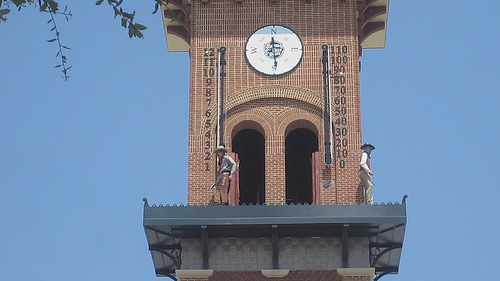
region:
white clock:
[221, 7, 297, 84]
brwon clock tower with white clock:
[183, 9, 378, 196]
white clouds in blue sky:
[91, 77, 135, 130]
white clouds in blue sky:
[59, 171, 95, 190]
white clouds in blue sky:
[10, 209, 73, 247]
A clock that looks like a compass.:
[245, 24, 302, 77]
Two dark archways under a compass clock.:
[228, 113, 321, 206]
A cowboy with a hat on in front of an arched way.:
[210, 143, 235, 203]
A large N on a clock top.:
[267, 25, 273, 35]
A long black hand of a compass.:
[267, 35, 274, 65]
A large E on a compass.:
[290, 46, 300, 51]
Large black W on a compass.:
[251, 45, 257, 55]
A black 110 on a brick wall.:
[329, 44, 348, 54]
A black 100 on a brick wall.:
[331, 53, 348, 64]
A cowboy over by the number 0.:
[356, 141, 375, 205]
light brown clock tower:
[148, 8, 406, 241]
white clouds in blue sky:
[123, 98, 169, 148]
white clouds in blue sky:
[42, 113, 118, 157]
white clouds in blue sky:
[367, 94, 444, 144]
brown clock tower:
[170, 8, 387, 273]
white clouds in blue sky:
[119, 98, 169, 142]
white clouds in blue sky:
[51, 140, 143, 172]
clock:
[234, 10, 322, 80]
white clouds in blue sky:
[20, 85, 77, 133]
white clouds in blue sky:
[413, 26, 475, 58]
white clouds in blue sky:
[393, 78, 444, 125]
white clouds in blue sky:
[390, 129, 420, 163]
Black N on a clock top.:
[268, 26, 277, 37]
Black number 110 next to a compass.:
[329, 45, 347, 55]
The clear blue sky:
[5, 19, 499, 270]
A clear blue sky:
[4, 15, 499, 265]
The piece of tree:
[1, 15, 148, 84]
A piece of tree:
[4, 14, 149, 71]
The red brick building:
[148, 15, 433, 277]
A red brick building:
[130, 13, 442, 268]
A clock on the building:
[233, 25, 310, 79]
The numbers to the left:
[187, 40, 234, 187]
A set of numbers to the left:
[192, 31, 224, 179]